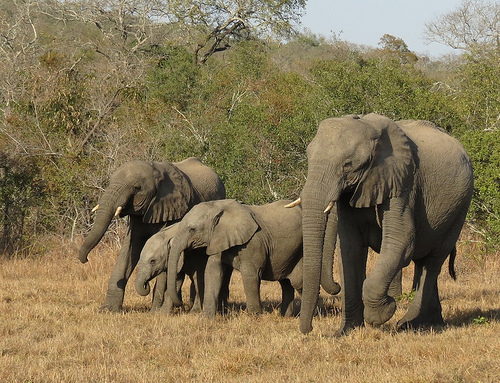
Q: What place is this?
A: It is a forest.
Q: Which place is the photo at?
A: It is at the forest.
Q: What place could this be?
A: It is a forest.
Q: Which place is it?
A: It is a forest.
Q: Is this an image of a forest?
A: Yes, it is showing a forest.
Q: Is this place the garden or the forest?
A: It is the forest.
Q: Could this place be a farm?
A: No, it is a forest.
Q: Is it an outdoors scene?
A: Yes, it is outdoors.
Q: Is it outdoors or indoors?
A: It is outdoors.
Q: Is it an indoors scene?
A: No, it is outdoors.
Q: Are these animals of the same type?
A: Yes, all the animals are elephants.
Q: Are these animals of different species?
A: No, all the animals are elephants.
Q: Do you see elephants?
A: Yes, there is an elephant.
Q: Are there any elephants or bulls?
A: Yes, there is an elephant.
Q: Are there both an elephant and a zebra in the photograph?
A: No, there is an elephant but no zebras.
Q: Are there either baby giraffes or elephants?
A: Yes, there is a baby elephant.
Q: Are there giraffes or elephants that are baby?
A: Yes, the elephant is a baby.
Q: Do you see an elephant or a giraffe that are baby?
A: Yes, the elephant is a baby.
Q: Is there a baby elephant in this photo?
A: Yes, there is a baby elephant.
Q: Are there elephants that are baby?
A: Yes, there is an elephant that is a baby.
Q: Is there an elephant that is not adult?
A: Yes, there is an baby elephant.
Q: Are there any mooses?
A: No, there are no mooses.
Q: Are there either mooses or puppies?
A: No, there are no mooses or puppies.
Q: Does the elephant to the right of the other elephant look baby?
A: Yes, the elephant is a baby.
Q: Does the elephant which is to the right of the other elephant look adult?
A: No, the elephant is a baby.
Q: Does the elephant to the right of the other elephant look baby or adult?
A: The elephant is a baby.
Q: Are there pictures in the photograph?
A: No, there are no pictures.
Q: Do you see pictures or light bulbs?
A: No, there are no pictures or light bulbs.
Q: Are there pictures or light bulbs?
A: No, there are no pictures or light bulbs.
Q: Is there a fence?
A: No, there are no fences.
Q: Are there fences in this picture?
A: No, there are no fences.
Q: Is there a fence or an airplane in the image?
A: No, there are no fences or airplanes.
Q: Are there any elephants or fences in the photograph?
A: Yes, there is an elephant.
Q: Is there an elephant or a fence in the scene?
A: Yes, there is an elephant.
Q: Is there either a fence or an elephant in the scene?
A: Yes, there is an elephant.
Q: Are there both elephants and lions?
A: No, there is an elephant but no lions.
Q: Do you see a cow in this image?
A: No, there are no cows.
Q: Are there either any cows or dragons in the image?
A: No, there are no cows or dragons.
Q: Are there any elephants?
A: Yes, there is an elephant.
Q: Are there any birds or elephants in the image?
A: Yes, there is an elephant.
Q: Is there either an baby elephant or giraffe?
A: Yes, there is a baby elephant.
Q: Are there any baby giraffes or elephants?
A: Yes, there is a baby elephant.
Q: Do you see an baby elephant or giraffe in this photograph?
A: Yes, there is a baby elephant.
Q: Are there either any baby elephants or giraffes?
A: Yes, there is a baby elephant.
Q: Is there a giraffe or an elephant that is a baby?
A: Yes, the elephant is a baby.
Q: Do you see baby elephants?
A: Yes, there is a baby elephant.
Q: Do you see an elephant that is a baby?
A: Yes, there is a baby elephant.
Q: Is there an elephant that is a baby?
A: Yes, there is an elephant that is a baby.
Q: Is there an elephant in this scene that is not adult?
A: Yes, there is an baby elephant.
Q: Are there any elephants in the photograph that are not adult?
A: Yes, there is an baby elephant.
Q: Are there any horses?
A: No, there are no horses.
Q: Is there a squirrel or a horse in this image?
A: No, there are no horses or squirrels.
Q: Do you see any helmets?
A: No, there are no helmets.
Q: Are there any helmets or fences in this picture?
A: No, there are no helmets or fences.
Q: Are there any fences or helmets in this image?
A: No, there are no helmets or fences.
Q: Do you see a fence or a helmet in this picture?
A: No, there are no helmets or fences.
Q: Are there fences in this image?
A: No, there are no fences.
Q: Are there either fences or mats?
A: No, there are no fences or mats.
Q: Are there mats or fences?
A: No, there are no fences or mats.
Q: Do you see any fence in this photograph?
A: No, there are no fences.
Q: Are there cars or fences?
A: No, there are no fences or cars.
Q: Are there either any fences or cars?
A: No, there are no fences or cars.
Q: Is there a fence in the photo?
A: No, there are no fences.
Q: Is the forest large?
A: Yes, the forest is large.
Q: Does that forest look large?
A: Yes, the forest is large.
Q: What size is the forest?
A: The forest is large.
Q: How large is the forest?
A: The forest is large.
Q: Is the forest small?
A: No, the forest is large.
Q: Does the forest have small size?
A: No, the forest is large.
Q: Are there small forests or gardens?
A: No, there is a forest but it is large.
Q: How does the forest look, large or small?
A: The forest is large.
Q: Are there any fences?
A: No, there are no fences.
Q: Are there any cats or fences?
A: No, there are no fences or cats.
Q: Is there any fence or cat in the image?
A: No, there are no fences or cats.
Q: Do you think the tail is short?
A: Yes, the tail is short.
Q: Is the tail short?
A: Yes, the tail is short.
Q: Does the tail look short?
A: Yes, the tail is short.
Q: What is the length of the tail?
A: The tail is short.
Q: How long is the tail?
A: The tail is short.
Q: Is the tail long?
A: No, the tail is short.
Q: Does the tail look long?
A: No, the tail is short.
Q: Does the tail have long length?
A: No, the tail is short.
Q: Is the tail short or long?
A: The tail is short.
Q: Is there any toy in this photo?
A: No, there are no toys.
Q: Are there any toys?
A: No, there are no toys.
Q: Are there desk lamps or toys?
A: No, there are no toys or desk lamps.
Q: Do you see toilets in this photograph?
A: No, there are no toilets.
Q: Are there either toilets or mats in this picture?
A: No, there are no toilets or mats.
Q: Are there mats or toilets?
A: No, there are no toilets or mats.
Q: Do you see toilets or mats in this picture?
A: No, there are no toilets or mats.